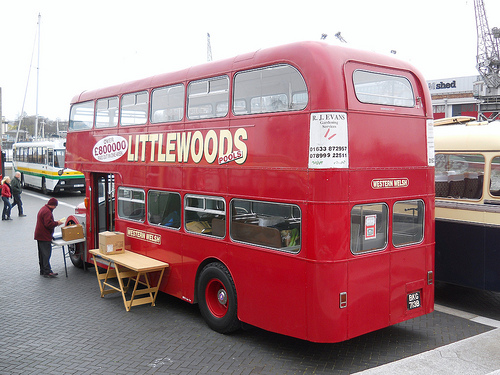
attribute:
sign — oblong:
[90, 134, 128, 163]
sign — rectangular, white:
[306, 110, 351, 171]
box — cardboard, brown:
[98, 230, 126, 257]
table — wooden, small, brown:
[86, 249, 168, 314]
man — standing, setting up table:
[34, 196, 65, 277]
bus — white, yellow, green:
[10, 140, 85, 197]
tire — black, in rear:
[194, 259, 244, 336]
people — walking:
[1, 170, 29, 222]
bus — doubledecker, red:
[65, 41, 439, 344]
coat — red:
[35, 205, 58, 243]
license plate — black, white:
[405, 291, 423, 310]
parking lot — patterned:
[1, 169, 500, 374]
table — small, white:
[49, 231, 90, 280]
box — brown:
[60, 223, 85, 242]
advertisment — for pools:
[125, 127, 249, 167]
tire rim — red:
[204, 277, 228, 319]